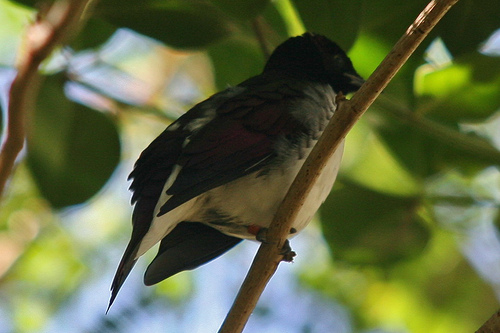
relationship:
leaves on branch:
[0, 1, 499, 330] [220, 0, 450, 330]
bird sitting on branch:
[105, 13, 381, 317] [220, 0, 450, 330]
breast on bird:
[266, 101, 346, 234] [121, 31, 372, 295]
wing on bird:
[90, 82, 248, 306] [105, 13, 381, 317]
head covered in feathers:
[267, 24, 371, 102] [294, 42, 306, 59]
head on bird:
[267, 24, 371, 102] [105, 13, 381, 317]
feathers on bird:
[294, 42, 306, 59] [105, 13, 381, 317]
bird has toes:
[105, 13, 381, 317] [272, 235, 297, 262]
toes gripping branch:
[272, 235, 297, 262] [220, 0, 450, 330]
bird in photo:
[108, 25, 366, 315] [2, 2, 499, 329]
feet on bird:
[253, 229, 295, 261] [105, 13, 381, 317]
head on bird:
[267, 24, 371, 102] [83, 2, 393, 296]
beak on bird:
[346, 74, 362, 95] [108, 25, 366, 315]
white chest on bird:
[305, 123, 344, 203] [105, 13, 381, 317]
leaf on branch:
[24, 70, 120, 210] [1, 3, 102, 193]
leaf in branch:
[402, 44, 498, 116] [220, 0, 450, 330]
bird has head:
[108, 25, 366, 315] [266, 26, 366, 92]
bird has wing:
[105, 13, 381, 317] [158, 85, 293, 219]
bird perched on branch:
[105, 23, 376, 317] [220, 0, 450, 330]